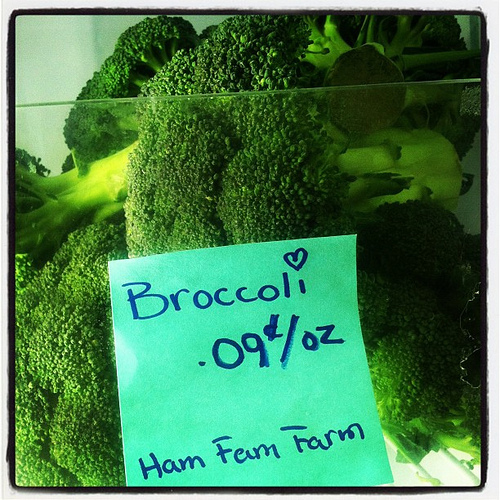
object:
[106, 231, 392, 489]
note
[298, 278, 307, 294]
i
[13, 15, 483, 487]
broccoli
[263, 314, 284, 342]
sign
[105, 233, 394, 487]
letter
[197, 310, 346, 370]
price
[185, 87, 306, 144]
glass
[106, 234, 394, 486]
card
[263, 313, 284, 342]
writing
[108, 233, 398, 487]
paper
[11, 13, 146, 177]
wall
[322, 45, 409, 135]
base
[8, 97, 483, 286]
panel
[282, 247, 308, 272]
heart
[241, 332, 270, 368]
number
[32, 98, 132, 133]
edge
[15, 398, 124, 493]
edge